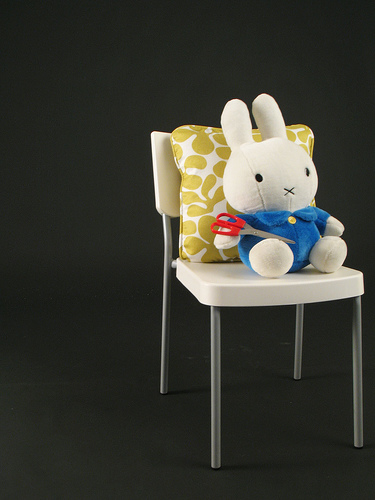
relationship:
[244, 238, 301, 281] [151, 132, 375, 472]
foot on chair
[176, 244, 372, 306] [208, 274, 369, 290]
seat has edge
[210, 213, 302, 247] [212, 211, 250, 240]
scissors have handle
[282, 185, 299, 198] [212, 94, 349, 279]
nose on teddy bear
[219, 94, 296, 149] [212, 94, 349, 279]
ears on teddy bear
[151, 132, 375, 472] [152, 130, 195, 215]
chair has back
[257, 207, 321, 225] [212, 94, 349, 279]
tie on teddy bear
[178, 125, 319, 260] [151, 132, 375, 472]
pillow on chair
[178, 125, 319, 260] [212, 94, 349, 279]
pillow behind teddy bear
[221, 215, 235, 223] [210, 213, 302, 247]
holes on scissors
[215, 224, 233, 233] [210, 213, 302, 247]
holes on scissors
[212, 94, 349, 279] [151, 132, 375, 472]
teddy bear on chair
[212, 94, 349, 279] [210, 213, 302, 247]
teddy bear holding scissors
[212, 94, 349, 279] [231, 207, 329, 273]
teddy bear has clothes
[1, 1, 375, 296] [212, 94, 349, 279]
wall behind teddy bear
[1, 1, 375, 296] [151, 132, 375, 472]
wall behind chair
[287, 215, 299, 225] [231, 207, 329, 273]
button on clothes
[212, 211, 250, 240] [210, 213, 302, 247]
handle on scissors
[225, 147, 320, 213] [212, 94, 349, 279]
face on teddy bear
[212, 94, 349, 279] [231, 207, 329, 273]
teddy bear wearing clothes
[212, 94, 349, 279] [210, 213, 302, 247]
teddy bear with scissors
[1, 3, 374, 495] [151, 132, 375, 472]
room has chair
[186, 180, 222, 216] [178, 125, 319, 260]
flower on pillow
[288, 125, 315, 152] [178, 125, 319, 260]
flower on pillow